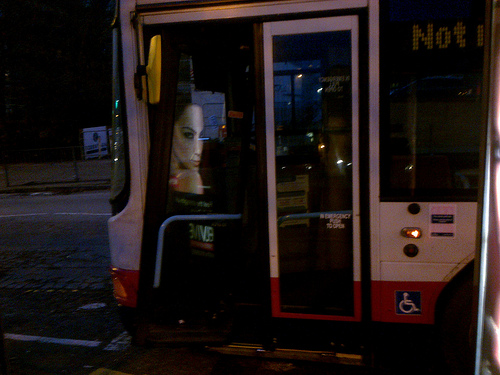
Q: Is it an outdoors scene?
A: Yes, it is outdoors.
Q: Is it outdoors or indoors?
A: It is outdoors.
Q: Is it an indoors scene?
A: No, it is outdoors.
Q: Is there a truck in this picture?
A: No, there are no trucks.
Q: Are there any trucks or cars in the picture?
A: No, there are no trucks or cars.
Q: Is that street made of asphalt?
A: Yes, the street is made of asphalt.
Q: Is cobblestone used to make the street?
A: No, the street is made of asphalt.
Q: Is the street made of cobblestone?
A: No, the street is made of asphalt.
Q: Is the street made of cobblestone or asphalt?
A: The street is made of asphalt.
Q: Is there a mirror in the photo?
A: Yes, there is a mirror.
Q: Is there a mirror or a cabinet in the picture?
A: Yes, there is a mirror.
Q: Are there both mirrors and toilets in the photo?
A: No, there is a mirror but no toilets.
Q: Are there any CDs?
A: No, there are no cds.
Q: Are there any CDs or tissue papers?
A: No, there are no CDs or tissue papers.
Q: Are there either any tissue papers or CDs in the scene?
A: No, there are no CDs or tissue papers.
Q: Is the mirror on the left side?
A: Yes, the mirror is on the left of the image.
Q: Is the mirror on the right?
A: No, the mirror is on the left of the image.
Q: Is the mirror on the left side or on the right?
A: The mirror is on the left of the image.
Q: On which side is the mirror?
A: The mirror is on the left of the image.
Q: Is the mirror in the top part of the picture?
A: Yes, the mirror is in the top of the image.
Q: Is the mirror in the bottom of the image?
A: No, the mirror is in the top of the image.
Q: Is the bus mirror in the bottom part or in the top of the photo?
A: The mirror is in the top of the image.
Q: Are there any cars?
A: No, there are no cars.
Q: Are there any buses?
A: Yes, there is a bus.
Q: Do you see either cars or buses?
A: Yes, there is a bus.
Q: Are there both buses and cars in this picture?
A: No, there is a bus but no cars.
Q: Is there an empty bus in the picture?
A: Yes, there is an empty bus.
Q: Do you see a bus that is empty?
A: Yes, there is a bus that is empty.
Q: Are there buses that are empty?
A: Yes, there is a bus that is empty.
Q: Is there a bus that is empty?
A: Yes, there is a bus that is empty.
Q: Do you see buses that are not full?
A: Yes, there is a empty bus.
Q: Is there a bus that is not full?
A: Yes, there is a empty bus.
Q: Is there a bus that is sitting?
A: Yes, there is a bus that is sitting.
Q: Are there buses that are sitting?
A: Yes, there is a bus that is sitting.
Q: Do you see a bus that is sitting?
A: Yes, there is a bus that is sitting.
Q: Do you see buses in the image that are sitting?
A: Yes, there is a bus that is sitting.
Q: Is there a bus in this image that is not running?
A: Yes, there is a bus that is sitting.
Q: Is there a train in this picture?
A: No, there are no trains.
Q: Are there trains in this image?
A: No, there are no trains.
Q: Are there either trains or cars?
A: No, there are no trains or cars.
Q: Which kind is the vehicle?
A: The vehicle is a bus.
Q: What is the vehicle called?
A: The vehicle is a bus.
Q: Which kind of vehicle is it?
A: The vehicle is a bus.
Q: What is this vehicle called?
A: This is a bus.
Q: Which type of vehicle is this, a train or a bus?
A: This is a bus.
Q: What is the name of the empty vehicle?
A: The vehicle is a bus.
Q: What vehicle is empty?
A: The vehicle is a bus.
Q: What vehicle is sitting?
A: The vehicle is a bus.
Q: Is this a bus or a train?
A: This is a bus.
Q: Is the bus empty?
A: Yes, the bus is empty.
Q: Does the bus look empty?
A: Yes, the bus is empty.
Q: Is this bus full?
A: No, the bus is empty.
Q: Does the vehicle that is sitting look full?
A: No, the bus is empty.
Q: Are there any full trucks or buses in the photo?
A: No, there is a bus but it is empty.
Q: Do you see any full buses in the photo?
A: No, there is a bus but it is empty.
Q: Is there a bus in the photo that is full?
A: No, there is a bus but it is empty.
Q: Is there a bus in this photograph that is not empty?
A: No, there is a bus but it is empty.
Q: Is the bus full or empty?
A: The bus is empty.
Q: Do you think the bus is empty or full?
A: The bus is empty.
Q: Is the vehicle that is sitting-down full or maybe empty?
A: The bus is empty.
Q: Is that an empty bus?
A: Yes, that is an empty bus.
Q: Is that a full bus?
A: No, that is an empty bus.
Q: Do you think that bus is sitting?
A: Yes, the bus is sitting.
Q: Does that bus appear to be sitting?
A: Yes, the bus is sitting.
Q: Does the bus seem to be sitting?
A: Yes, the bus is sitting.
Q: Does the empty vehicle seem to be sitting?
A: Yes, the bus is sitting.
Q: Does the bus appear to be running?
A: No, the bus is sitting.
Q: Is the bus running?
A: No, the bus is sitting.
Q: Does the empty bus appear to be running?
A: No, the bus is sitting.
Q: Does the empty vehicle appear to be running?
A: No, the bus is sitting.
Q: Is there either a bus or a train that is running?
A: No, there is a bus but it is sitting.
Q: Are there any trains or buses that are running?
A: No, there is a bus but it is sitting.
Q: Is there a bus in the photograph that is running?
A: No, there is a bus but it is sitting.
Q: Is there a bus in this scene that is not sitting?
A: No, there is a bus but it is sitting.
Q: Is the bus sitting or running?
A: The bus is sitting.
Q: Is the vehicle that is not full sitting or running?
A: The bus is sitting.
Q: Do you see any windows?
A: Yes, there is a window.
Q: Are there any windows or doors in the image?
A: Yes, there is a window.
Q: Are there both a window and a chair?
A: No, there is a window but no chairs.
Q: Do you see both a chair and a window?
A: No, there is a window but no chairs.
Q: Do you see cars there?
A: No, there are no cars.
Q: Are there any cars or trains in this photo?
A: No, there are no cars or trains.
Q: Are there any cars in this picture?
A: No, there are no cars.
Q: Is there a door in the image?
A: Yes, there is a door.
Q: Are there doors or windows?
A: Yes, there is a door.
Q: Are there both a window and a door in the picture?
A: Yes, there are both a door and a window.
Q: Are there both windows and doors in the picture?
A: Yes, there are both a door and a window.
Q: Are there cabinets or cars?
A: No, there are no cars or cabinets.